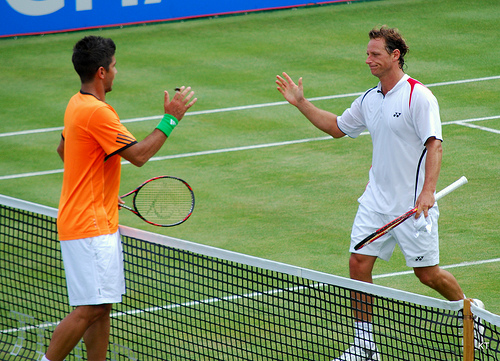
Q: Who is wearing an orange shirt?
A: Guy on the left.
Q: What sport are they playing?
A: Tennis.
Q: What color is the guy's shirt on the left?
A: Orange.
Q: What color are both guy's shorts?
A: White.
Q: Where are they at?
A: Tennis court.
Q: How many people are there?
A: Two.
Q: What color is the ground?
A: Green.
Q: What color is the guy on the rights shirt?
A: White.